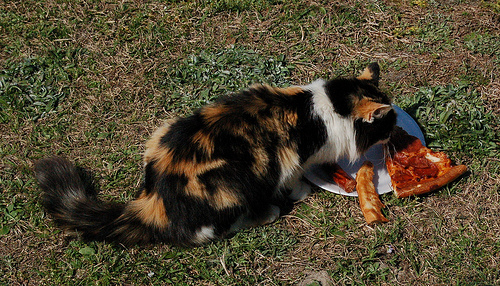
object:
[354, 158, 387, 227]
pizza crust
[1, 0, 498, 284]
grass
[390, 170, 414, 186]
pepperoni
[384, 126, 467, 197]
pizza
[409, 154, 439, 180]
pepperoni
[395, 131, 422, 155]
pepperoni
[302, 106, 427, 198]
plate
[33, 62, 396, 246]
cat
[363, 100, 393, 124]
ear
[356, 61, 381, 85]
ear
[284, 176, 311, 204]
paw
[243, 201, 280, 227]
paw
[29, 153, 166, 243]
tail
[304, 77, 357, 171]
neck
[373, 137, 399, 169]
whiskers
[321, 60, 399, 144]
head